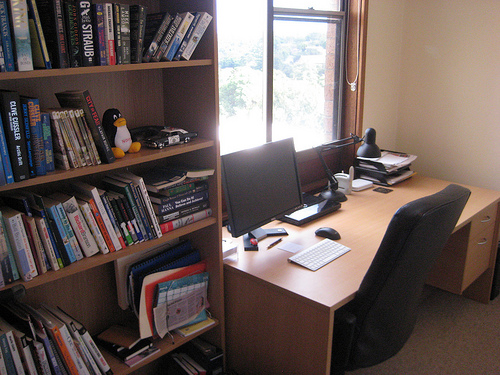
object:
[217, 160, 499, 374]
desk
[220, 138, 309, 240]
monitor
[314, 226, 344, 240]
mouse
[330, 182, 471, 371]
chair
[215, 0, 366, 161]
window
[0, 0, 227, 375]
shelf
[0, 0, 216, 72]
books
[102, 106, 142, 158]
penguin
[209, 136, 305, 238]
computer monitor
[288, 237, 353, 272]
keyboard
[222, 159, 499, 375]
desk